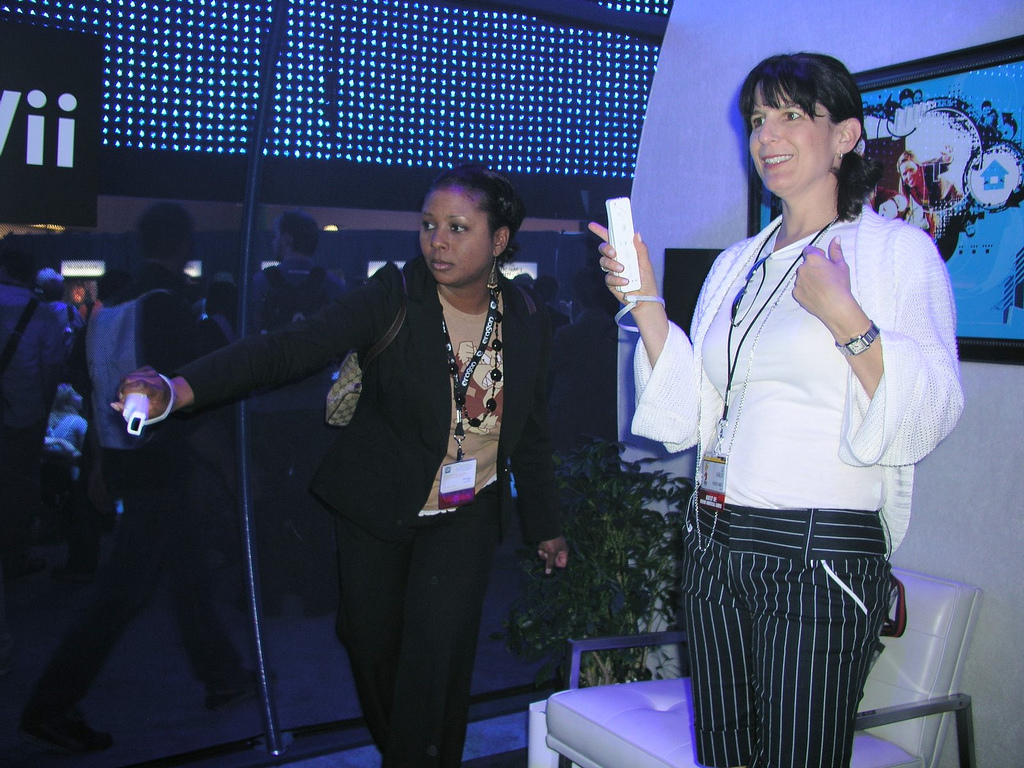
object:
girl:
[110, 164, 568, 768]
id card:
[438, 458, 477, 509]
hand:
[792, 235, 850, 317]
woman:
[588, 51, 965, 768]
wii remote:
[605, 196, 643, 293]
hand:
[109, 365, 177, 423]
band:
[143, 373, 176, 426]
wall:
[3, 0, 696, 223]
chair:
[544, 559, 987, 767]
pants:
[332, 484, 497, 768]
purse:
[326, 265, 406, 427]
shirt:
[629, 207, 965, 560]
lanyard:
[699, 216, 858, 510]